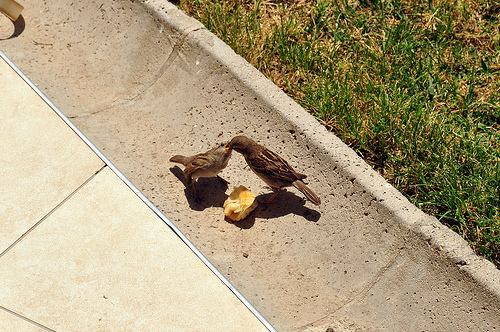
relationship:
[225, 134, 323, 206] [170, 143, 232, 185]
bird kissing bird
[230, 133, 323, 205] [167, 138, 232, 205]
fird kissing fird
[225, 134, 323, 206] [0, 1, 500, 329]
bird on curb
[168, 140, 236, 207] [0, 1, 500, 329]
bird on curb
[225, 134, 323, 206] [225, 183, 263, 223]
bird by food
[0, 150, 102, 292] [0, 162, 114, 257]
concreter has crack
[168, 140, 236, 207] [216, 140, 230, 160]
bird has head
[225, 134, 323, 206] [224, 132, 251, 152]
bird has head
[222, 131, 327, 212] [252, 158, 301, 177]
bird has feathers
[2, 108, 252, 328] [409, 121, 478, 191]
tile on ground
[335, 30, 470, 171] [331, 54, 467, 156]
field has grass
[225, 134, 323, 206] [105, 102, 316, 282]
bird on ground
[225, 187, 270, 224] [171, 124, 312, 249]
food on ground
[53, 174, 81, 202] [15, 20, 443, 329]
crack on sidewalk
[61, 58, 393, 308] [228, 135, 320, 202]
sidewalk beneath bird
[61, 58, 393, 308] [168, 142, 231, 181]
sidewalk beneath bird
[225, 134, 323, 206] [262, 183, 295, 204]
bird has legs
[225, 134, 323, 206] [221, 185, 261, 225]
bird standing next to food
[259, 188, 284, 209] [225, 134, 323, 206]
talons of bird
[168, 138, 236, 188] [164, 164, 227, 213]
bird has shadow